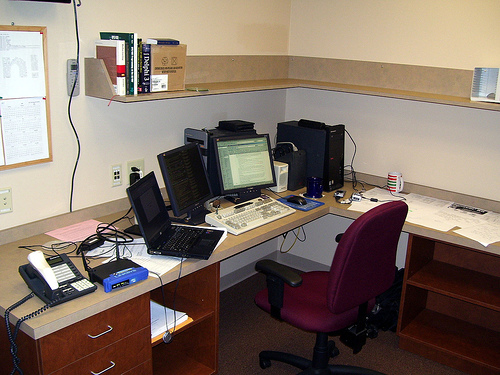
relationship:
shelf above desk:
[74, 51, 498, 112] [136, 189, 485, 313]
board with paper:
[0, 21, 55, 171] [0, 30, 48, 101]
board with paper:
[0, 21, 55, 171] [1, 99, 52, 168]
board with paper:
[0, 21, 55, 171] [0, 104, 8, 167]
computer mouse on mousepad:
[287, 196, 308, 206] [276, 194, 325, 212]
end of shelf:
[84, 52, 131, 107] [50, 9, 285, 128]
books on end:
[94, 30, 180, 96] [84, 52, 131, 107]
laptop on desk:
[126, 170, 225, 260] [0, 181, 500, 375]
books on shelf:
[94, 30, 180, 96] [83, 53, 289, 103]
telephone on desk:
[3, 250, 98, 375] [4, 185, 337, 373]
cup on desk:
[386, 171, 404, 196] [1, 181, 498, 342]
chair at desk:
[257, 193, 415, 366] [75, 187, 364, 242]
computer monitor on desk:
[213, 130, 275, 193] [0, 183, 328, 343]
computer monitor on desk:
[155, 142, 212, 213] [0, 183, 328, 343]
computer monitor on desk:
[127, 172, 170, 239] [0, 183, 328, 343]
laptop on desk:
[118, 166, 233, 270] [4, 185, 337, 373]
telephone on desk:
[3, 250, 98, 375] [0, 183, 328, 343]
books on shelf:
[96, 25, 196, 104] [74, 51, 498, 112]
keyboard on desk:
[202, 185, 319, 246] [4, 185, 337, 373]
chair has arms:
[254, 200, 410, 375] [249, 224, 354, 289]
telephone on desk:
[16, 240, 94, 315] [4, 145, 352, 342]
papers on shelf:
[120, 292, 215, 338] [142, 258, 225, 369]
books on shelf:
[94, 30, 180, 96] [84, 90, 204, 102]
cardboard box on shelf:
[149, 42, 186, 86] [97, 74, 498, 112]